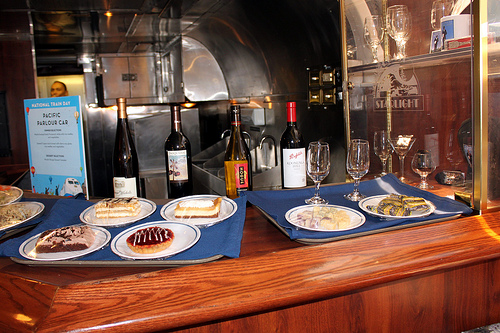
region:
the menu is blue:
[25, 97, 95, 206]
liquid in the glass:
[311, 159, 325, 182]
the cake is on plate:
[97, 196, 140, 220]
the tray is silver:
[89, 255, 202, 267]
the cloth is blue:
[197, 228, 234, 260]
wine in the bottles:
[105, 96, 256, 192]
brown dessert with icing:
[132, 219, 192, 281]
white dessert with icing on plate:
[178, 183, 228, 230]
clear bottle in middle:
[228, 95, 250, 202]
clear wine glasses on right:
[305, 120, 400, 197]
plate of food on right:
[278, 193, 368, 245]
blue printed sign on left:
[28, 88, 96, 187]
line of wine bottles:
[104, 78, 311, 216]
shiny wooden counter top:
[110, 272, 319, 312]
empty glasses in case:
[355, 8, 415, 40]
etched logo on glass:
[355, 56, 432, 133]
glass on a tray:
[290, 140, 333, 197]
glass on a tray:
[345, 127, 372, 193]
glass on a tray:
[375, 118, 397, 176]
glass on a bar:
[411, 147, 451, 190]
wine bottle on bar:
[265, 91, 306, 196]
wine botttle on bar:
[218, 90, 268, 197]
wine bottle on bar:
[160, 91, 186, 191]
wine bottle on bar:
[111, 96, 146, 201]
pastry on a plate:
[127, 221, 172, 256]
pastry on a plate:
[174, 193, 224, 222]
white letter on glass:
[372, 98, 382, 110]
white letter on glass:
[378, 98, 384, 110]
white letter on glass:
[382, 98, 389, 111]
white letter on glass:
[386, 97, 393, 108]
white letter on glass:
[398, 98, 404, 108]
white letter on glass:
[399, 97, 407, 109]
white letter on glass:
[406, 95, 412, 109]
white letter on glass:
[410, 95, 418, 107]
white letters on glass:
[373, 97, 420, 111]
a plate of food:
[376, 183, 449, 243]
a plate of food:
[178, 187, 229, 234]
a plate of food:
[139, 218, 191, 268]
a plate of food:
[104, 195, 169, 230]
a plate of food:
[35, 223, 100, 270]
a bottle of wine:
[108, 90, 135, 170]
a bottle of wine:
[155, 102, 220, 216]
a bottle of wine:
[204, 63, 308, 245]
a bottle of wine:
[271, 103, 330, 213]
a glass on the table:
[289, 133, 332, 199]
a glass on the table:
[344, 135, 384, 200]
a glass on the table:
[373, 125, 392, 175]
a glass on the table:
[389, 128, 409, 185]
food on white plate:
[0, 200, 25, 220]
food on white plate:
[0, 183, 18, 201]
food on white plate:
[35, 223, 94, 252]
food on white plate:
[92, 194, 143, 215]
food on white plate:
[127, 225, 177, 255]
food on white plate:
[173, 199, 227, 221]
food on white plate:
[298, 208, 349, 229]